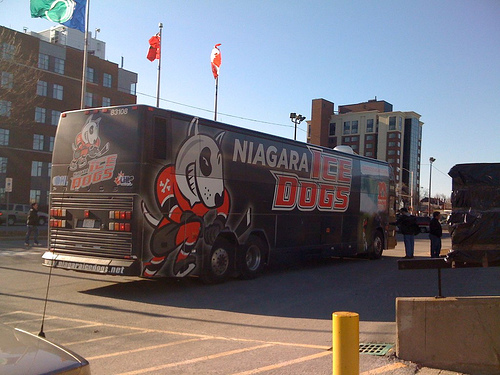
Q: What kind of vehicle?
A: Bus.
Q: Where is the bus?
A: On the street.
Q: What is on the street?
A: A bus.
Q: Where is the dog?
A: On the bus.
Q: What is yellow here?
A: A pole.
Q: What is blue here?
A: The sky.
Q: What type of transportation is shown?
A: A bus.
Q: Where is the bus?
A: In a parking lot.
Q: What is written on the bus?
A: Niagara Ice Dogs.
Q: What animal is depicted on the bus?
A: A dog.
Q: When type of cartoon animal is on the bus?
A: Dog.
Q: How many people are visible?
A: Three.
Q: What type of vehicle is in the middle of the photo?
A: Bus.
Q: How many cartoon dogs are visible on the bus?
A: Two.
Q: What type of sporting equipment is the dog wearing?
A: Hockey.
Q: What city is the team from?
A: Niagara.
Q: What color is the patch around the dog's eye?
A: Black.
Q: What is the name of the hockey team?
A: Ice Dogs.